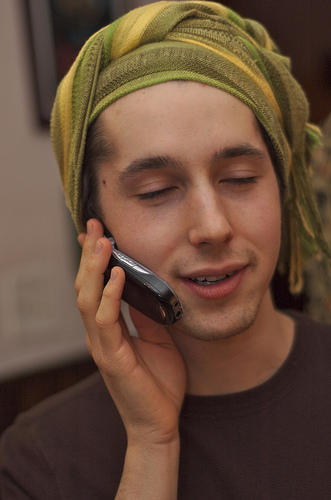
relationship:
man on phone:
[1, 1, 329, 498] [106, 237, 184, 328]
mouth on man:
[174, 259, 255, 302] [1, 1, 329, 498]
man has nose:
[1, 1, 329, 498] [189, 170, 234, 247]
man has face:
[1, 1, 329, 498] [77, 79, 285, 338]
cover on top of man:
[49, 0, 330, 294] [1, 1, 329, 498]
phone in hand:
[106, 237, 184, 328] [73, 219, 187, 443]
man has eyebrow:
[1, 1, 329, 498] [122, 154, 183, 179]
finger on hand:
[93, 267, 132, 361] [73, 219, 187, 443]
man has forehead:
[1, 1, 329, 498] [82, 78, 266, 161]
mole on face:
[101, 175, 109, 185] [77, 79, 285, 338]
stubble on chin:
[175, 288, 271, 342] [189, 314, 256, 338]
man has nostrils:
[1, 1, 329, 498] [194, 233, 237, 250]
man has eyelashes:
[1, 1, 329, 498] [135, 182, 176, 200]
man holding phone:
[1, 1, 329, 498] [106, 237, 184, 328]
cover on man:
[49, 0, 330, 294] [1, 1, 329, 498]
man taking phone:
[1, 1, 329, 498] [106, 237, 184, 328]